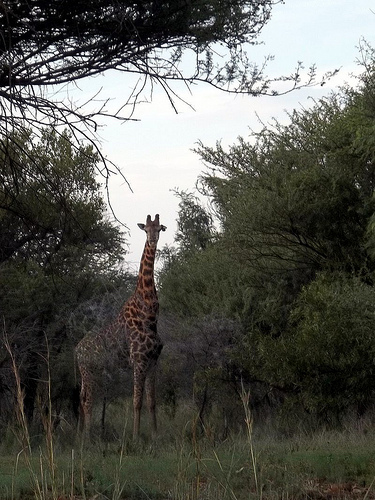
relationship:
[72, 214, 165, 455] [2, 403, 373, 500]
giraffe standing in field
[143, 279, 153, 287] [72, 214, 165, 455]
spot on giraffe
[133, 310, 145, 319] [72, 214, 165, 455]
spot on giraffe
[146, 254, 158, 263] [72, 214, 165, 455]
spot on giraffe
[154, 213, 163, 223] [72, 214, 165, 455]
ossicone on giraffe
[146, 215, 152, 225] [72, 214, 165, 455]
ossicone on giraffe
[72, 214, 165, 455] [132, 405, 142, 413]
giraffe has knee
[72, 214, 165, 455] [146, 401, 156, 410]
giraffe has knee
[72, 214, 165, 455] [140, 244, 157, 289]
giraffe has neck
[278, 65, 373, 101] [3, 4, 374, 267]
cloud in sky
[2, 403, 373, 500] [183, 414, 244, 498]
field of grass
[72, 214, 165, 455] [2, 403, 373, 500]
giraffe in field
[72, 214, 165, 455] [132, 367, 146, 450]
giraffe has leg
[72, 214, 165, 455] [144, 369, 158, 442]
giraffe has leg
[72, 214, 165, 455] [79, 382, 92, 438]
giraffe has leg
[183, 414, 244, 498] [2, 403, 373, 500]
grass in field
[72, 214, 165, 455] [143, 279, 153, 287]
giraffe has spot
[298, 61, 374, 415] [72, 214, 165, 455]
tree on side of giraffe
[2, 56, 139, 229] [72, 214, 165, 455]
branch above giraffe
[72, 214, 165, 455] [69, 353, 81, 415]
giraffe has tail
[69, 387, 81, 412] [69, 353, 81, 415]
hair on tail